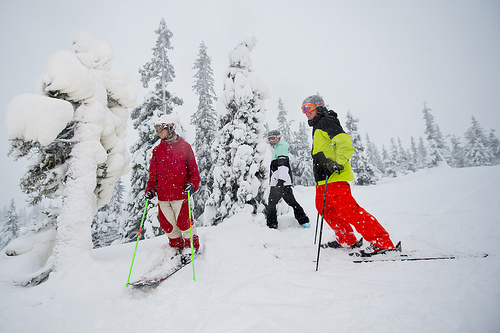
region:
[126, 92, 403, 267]
three skiers on a hill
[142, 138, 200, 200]
red jacket young boy is wearing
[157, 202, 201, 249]
red and white ski pants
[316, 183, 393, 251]
red ski pants worn by the woman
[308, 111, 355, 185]
woman wearing black and lime jacket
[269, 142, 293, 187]
man wearing a black, white and light aqua jacket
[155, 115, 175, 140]
white and black helmet worn by the young man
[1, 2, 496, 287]
snow covered trees in the back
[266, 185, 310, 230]
black ski pants worn by young boy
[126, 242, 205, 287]
skis worn by the skier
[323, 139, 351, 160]
the coat is lime green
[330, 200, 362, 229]
the pants are orange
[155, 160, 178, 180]
the coat is red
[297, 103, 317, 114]
the goggles are neon orange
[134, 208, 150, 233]
the pole is neon green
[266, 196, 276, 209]
the pants are black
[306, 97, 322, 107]
the helmet is gray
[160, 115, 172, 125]
the helmet is white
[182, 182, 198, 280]
bright neon green ski pole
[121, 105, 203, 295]
skier holding two neon ski poles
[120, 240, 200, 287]
a person on snow covered skis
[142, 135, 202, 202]
red coat on a skier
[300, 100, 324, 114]
neon orange goggles on a skier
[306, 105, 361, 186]
coat on a skier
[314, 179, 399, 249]
red pants on a skier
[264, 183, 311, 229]
dark colored pants on a skier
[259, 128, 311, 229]
skier on a snowy ground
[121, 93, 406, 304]
three skiers on a snow field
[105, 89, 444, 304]
three people that are skiing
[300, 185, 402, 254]
a pair of bright red ski pants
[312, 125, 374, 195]
a lime green snow coat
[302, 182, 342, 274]
a stick used for skiing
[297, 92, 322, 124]
a pair of red goggles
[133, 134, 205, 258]
a red and white matching snow suit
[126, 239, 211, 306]
a set of red skis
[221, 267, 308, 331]
freshly fallen white snow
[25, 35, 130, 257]
a fir tree with snow gathered on it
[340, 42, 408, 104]
the gray sky during a snowfall